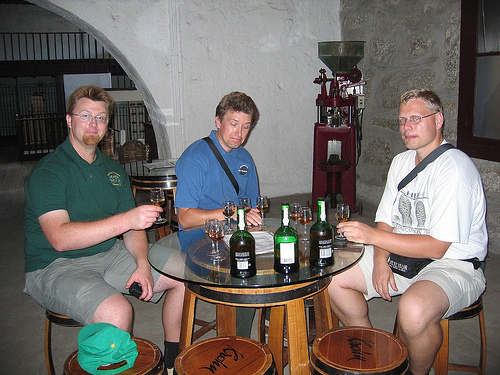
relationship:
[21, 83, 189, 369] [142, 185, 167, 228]
he holding glass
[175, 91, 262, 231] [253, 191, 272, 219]
man holding glass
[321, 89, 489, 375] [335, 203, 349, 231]
man holding glass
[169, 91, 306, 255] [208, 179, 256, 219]
man looking down at glass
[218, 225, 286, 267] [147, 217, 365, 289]
white paper sitting on edge table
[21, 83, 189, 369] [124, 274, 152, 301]
he holding object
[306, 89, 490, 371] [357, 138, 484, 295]
man wearing shirt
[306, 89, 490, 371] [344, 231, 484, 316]
man wearing short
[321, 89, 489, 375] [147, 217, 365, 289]
man at edge table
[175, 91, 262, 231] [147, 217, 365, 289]
man at edge table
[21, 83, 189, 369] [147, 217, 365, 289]
he at edge table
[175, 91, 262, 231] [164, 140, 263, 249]
man wearing shirt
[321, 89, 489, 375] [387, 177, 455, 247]
man wearing shirt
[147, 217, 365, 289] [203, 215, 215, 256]
edge table with glass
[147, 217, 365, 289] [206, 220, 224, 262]
edge table with glass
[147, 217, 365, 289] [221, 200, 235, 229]
edge table with glass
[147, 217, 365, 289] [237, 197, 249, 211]
edge table with glass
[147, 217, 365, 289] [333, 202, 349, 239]
edge table with glass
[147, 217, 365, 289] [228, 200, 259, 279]
edge table with bottle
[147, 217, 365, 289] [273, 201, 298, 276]
edge table with bottle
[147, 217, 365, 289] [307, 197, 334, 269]
edge table with bottle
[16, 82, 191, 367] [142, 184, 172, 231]
he holding wine